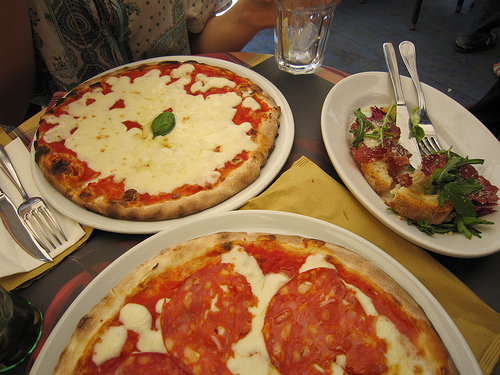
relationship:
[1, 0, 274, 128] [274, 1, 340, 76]
person holding glass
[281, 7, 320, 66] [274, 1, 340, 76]
ice cubes are in glass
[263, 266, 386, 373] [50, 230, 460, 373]
salami on pizza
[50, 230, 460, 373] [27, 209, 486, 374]
pizza on plate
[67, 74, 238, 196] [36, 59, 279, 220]
cheese on pizza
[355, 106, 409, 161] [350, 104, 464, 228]
salami on bread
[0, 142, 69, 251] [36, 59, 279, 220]
fork next to pizza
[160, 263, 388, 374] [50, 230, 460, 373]
pepperoni on pizza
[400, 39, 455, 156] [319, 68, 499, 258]
fork on plate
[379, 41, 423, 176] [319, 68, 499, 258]
knife on plate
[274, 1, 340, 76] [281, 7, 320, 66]
glass has ice cubes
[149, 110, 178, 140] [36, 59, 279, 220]
leaf on pizza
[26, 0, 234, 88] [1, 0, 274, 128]
shirt on lady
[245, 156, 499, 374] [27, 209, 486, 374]
place mat under plate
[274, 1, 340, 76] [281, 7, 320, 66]
glass with ice cubes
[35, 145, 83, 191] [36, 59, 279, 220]
bubbles are on pizza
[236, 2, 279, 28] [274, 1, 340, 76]
hand holding glass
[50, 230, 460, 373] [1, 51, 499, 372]
pizza on table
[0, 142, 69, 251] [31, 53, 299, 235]
fork next to plate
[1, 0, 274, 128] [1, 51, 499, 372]
person at table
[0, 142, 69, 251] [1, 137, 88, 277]
fork on napkin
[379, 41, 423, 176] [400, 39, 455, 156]
knife next to fork